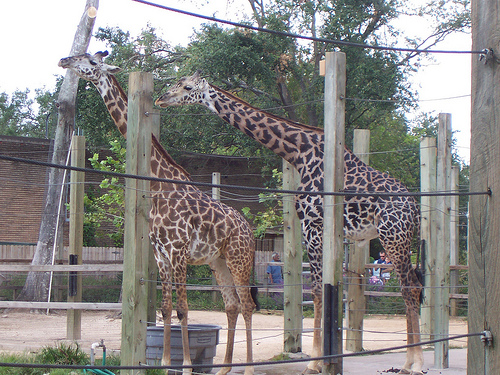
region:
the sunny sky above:
[3, 0, 494, 159]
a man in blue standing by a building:
[264, 255, 286, 291]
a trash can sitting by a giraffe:
[133, 315, 218, 373]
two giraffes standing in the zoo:
[56, 47, 424, 373]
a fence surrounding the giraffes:
[10, 77, 479, 373]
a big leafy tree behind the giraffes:
[154, 4, 396, 204]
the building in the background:
[3, 137, 326, 288]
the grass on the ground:
[3, 343, 125, 373]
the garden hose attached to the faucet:
[85, 341, 116, 373]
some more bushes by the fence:
[63, 271, 451, 316]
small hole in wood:
[479, 183, 499, 200]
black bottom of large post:
[312, 281, 362, 368]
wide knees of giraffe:
[211, 297, 274, 322]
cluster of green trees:
[7, 98, 56, 123]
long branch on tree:
[392, 47, 430, 67]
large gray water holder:
[134, 310, 236, 372]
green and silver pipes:
[76, 334, 116, 371]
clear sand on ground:
[23, 306, 135, 331]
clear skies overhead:
[6, 51, 41, 75]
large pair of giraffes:
[64, 53, 431, 360]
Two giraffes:
[42, 30, 231, 126]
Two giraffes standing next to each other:
[51, 32, 435, 373]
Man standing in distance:
[257, 245, 290, 307]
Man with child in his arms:
[360, 238, 398, 289]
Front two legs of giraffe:
[154, 263, 201, 374]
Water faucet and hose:
[77, 329, 112, 374]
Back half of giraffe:
[204, 200, 268, 374]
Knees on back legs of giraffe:
[211, 291, 261, 324]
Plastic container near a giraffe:
[145, 304, 226, 370]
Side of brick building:
[3, 160, 31, 259]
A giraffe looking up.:
[58, 42, 123, 92]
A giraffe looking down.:
[162, 75, 213, 117]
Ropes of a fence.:
[350, 90, 485, 190]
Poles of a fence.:
[115, 75, 166, 350]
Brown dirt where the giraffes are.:
[10, 315, 65, 340]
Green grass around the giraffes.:
[38, 351, 98, 369]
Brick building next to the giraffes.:
[11, 147, 288, 229]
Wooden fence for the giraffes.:
[14, 254, 138, 279]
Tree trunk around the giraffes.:
[23, 80, 80, 313]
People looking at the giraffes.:
[368, 250, 396, 285]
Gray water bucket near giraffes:
[142, 320, 219, 373]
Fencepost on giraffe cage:
[321, 46, 343, 373]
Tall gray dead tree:
[25, 10, 90, 295]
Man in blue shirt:
[262, 251, 282, 282]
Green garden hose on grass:
[81, 335, 111, 370]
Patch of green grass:
[0, 336, 117, 371]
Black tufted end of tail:
[250, 280, 265, 306]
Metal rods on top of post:
[65, 121, 85, 133]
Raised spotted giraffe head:
[55, 45, 115, 75]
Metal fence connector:
[476, 41, 487, 61]